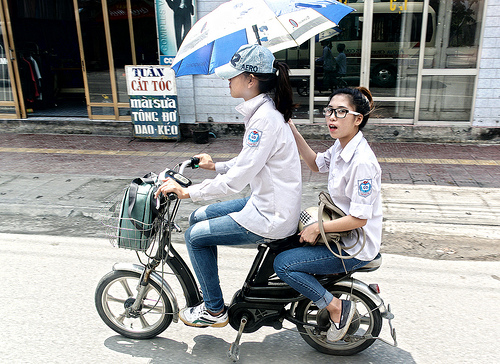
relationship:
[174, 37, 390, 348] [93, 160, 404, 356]
people riding scooter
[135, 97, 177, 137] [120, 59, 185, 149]
letter on sign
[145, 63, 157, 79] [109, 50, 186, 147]
letter on sign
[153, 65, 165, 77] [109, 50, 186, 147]
letter on sign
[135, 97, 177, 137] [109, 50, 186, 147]
letter on sign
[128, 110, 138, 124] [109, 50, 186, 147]
letter on sign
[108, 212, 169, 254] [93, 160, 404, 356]
basket on front of scooter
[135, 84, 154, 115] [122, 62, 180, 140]
letter on sign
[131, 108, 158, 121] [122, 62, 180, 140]
letter on sign